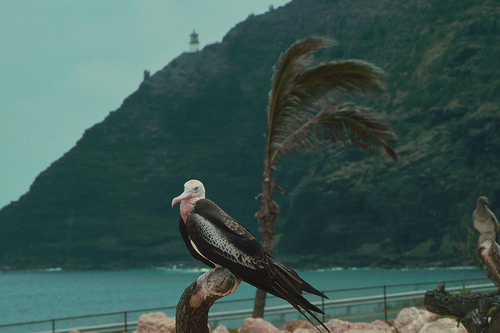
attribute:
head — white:
[246, 302, 316, 331]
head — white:
[169, 175, 208, 230]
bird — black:
[167, 173, 336, 331]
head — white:
[172, 179, 220, 206]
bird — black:
[128, 171, 299, 298]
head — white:
[165, 175, 217, 217]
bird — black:
[139, 176, 343, 328]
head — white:
[462, 193, 496, 231]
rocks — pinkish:
[120, 292, 476, 331]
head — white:
[170, 179, 204, 209]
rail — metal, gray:
[18, 279, 499, 331]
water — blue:
[24, 272, 131, 309]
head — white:
[164, 172, 211, 224]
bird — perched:
[468, 194, 499, 242]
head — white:
[166, 175, 209, 207]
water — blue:
[26, 274, 108, 309]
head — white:
[157, 156, 220, 221]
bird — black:
[96, 135, 351, 326]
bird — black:
[466, 192, 498, 249]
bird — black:
[140, 182, 326, 289]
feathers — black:
[153, 210, 305, 297]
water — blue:
[2, 271, 177, 306]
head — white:
[166, 179, 203, 202]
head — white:
[168, 177, 208, 219]